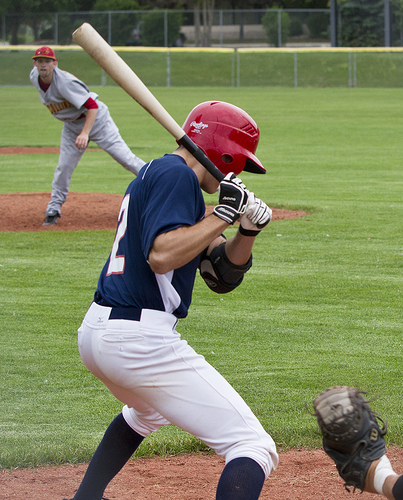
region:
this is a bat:
[77, 26, 166, 122]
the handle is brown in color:
[198, 152, 218, 175]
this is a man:
[31, 49, 85, 146]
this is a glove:
[222, 188, 234, 208]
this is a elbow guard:
[205, 272, 232, 297]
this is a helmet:
[194, 103, 239, 136]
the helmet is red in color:
[212, 117, 236, 136]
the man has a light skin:
[167, 237, 192, 251]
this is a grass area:
[315, 222, 401, 337]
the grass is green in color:
[301, 96, 362, 152]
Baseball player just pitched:
[27, 43, 150, 223]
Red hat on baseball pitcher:
[29, 44, 55, 59]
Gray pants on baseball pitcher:
[44, 99, 143, 210]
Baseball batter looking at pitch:
[72, 97, 279, 496]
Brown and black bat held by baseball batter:
[72, 21, 266, 227]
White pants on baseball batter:
[74, 300, 278, 474]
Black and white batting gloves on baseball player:
[215, 168, 272, 234]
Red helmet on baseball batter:
[176, 97, 267, 179]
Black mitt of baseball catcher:
[307, 382, 384, 485]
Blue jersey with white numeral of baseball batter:
[90, 151, 255, 318]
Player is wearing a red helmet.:
[159, 73, 290, 191]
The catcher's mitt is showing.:
[283, 360, 402, 493]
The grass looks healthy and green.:
[275, 232, 398, 372]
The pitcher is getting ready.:
[16, 37, 153, 240]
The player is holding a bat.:
[64, 14, 310, 332]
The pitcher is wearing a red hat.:
[12, 33, 149, 230]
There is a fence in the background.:
[143, 1, 400, 85]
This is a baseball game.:
[12, 16, 367, 382]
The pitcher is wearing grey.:
[17, 49, 153, 244]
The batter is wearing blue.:
[82, 56, 286, 345]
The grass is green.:
[107, 80, 396, 202]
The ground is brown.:
[7, 421, 389, 496]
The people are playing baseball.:
[18, 20, 282, 317]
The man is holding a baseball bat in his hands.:
[51, 10, 270, 235]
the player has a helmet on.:
[168, 86, 268, 204]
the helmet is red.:
[172, 82, 272, 188]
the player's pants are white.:
[42, 268, 298, 485]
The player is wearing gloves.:
[208, 161, 281, 244]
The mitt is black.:
[297, 366, 401, 489]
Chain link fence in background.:
[7, 28, 401, 99]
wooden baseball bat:
[62, 3, 274, 236]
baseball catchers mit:
[297, 372, 397, 495]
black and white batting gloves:
[200, 156, 303, 245]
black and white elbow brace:
[194, 215, 287, 314]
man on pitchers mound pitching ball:
[25, 37, 133, 229]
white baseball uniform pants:
[76, 276, 279, 482]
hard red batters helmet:
[172, 85, 273, 195]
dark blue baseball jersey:
[91, 140, 233, 362]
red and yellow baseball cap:
[27, 41, 62, 73]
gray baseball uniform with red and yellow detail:
[30, 70, 120, 235]